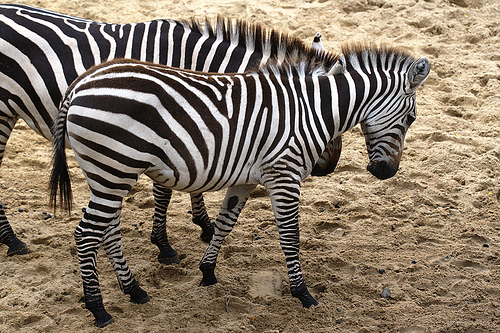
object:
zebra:
[47, 39, 433, 328]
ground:
[397, 264, 498, 325]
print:
[160, 265, 194, 284]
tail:
[47, 92, 73, 220]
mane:
[340, 42, 410, 63]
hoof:
[92, 310, 114, 329]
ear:
[407, 57, 431, 89]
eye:
[407, 114, 416, 125]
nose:
[388, 167, 399, 178]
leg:
[266, 175, 322, 308]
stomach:
[152, 164, 249, 193]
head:
[345, 40, 430, 180]